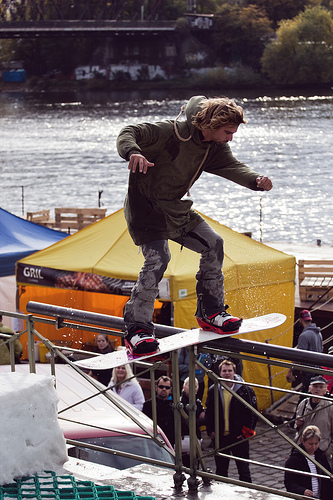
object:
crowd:
[86, 309, 333, 497]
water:
[0, 99, 333, 245]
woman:
[284, 424, 333, 499]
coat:
[284, 442, 333, 497]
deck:
[295, 281, 333, 321]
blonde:
[106, 345, 145, 412]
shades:
[157, 384, 173, 390]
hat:
[300, 309, 313, 321]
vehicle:
[0, 363, 176, 470]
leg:
[122, 238, 171, 325]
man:
[115, 95, 273, 357]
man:
[204, 359, 258, 483]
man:
[141, 375, 175, 448]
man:
[286, 309, 324, 431]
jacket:
[204, 375, 258, 439]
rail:
[0, 299, 333, 483]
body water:
[0, 88, 332, 246]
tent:
[15, 206, 296, 417]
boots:
[122, 318, 160, 356]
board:
[70, 312, 287, 370]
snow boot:
[196, 303, 243, 335]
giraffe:
[189, 94, 246, 134]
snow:
[0, 372, 69, 487]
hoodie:
[116, 95, 260, 246]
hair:
[191, 96, 246, 131]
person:
[177, 376, 206, 475]